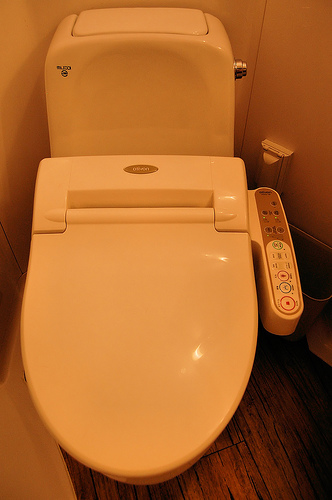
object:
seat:
[16, 149, 259, 490]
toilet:
[26, 150, 275, 484]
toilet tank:
[43, 6, 236, 156]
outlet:
[260, 136, 293, 200]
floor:
[255, 347, 331, 499]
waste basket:
[299, 222, 330, 296]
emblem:
[125, 162, 157, 173]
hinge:
[68, 202, 215, 229]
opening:
[69, 5, 209, 36]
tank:
[42, 5, 237, 159]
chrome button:
[234, 59, 246, 77]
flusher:
[232, 56, 247, 79]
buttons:
[266, 234, 297, 312]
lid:
[20, 187, 274, 490]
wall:
[207, 0, 329, 255]